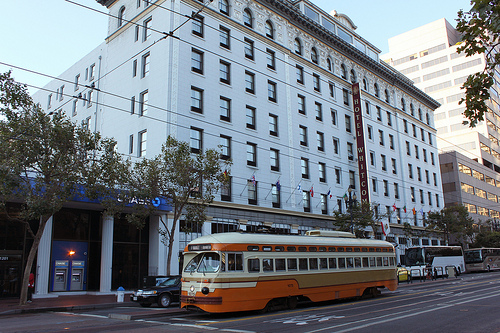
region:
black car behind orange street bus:
[128, 269, 186, 306]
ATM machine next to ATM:
[51, 260, 68, 292]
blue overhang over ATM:
[5, 173, 173, 213]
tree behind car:
[111, 135, 228, 274]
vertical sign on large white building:
[349, 80, 374, 220]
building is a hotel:
[16, 1, 447, 224]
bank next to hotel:
[3, 173, 175, 309]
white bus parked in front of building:
[403, 243, 466, 280]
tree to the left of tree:
[0, 70, 93, 310]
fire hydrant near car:
[114, 285, 126, 302]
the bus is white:
[400, 242, 480, 289]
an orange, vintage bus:
[164, 227, 400, 324]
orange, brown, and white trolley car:
[186, 234, 386, 299]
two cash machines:
[51, 259, 85, 291]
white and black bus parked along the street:
[410, 245, 463, 272]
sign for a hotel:
[353, 96, 365, 138]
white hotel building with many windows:
[205, 93, 427, 205]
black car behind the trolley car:
[133, 278, 178, 305]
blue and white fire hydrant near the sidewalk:
[116, 287, 127, 307]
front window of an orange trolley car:
[186, 253, 220, 272]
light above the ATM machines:
[68, 248, 73, 255]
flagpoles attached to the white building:
[220, 168, 335, 209]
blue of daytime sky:
[0, 2, 107, 82]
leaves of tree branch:
[451, 0, 496, 125]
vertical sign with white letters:
[349, 83, 374, 214]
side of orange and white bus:
[182, 234, 397, 316]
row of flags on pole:
[217, 169, 427, 224]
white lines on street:
[250, 277, 494, 329]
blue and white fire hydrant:
[114, 284, 127, 304]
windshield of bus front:
[185, 250, 222, 275]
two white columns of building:
[32, 203, 114, 300]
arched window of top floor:
[240, 5, 254, 26]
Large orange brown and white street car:
[176, 225, 402, 317]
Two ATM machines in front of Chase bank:
[52, 255, 86, 294]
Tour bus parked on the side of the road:
[398, 241, 473, 278]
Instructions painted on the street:
[261, 305, 348, 332]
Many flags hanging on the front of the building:
[206, 165, 436, 225]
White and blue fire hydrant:
[111, 283, 128, 305]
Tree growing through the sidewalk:
[0, 70, 122, 312]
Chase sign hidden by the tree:
[115, 188, 169, 209]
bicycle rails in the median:
[398, 263, 463, 284]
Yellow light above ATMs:
[65, 243, 77, 257]